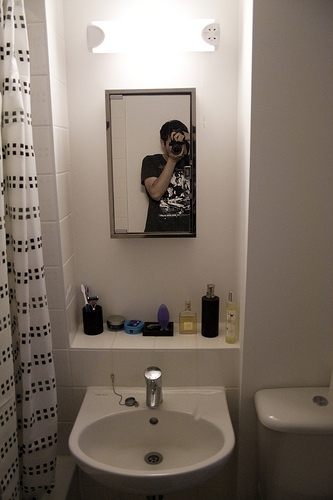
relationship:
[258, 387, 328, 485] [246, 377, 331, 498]
back of toilet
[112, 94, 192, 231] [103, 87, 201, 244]
mirror has frame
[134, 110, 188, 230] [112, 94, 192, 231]
reflection in mirror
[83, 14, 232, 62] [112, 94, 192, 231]
lights above mirror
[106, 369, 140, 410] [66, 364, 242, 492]
plug for sink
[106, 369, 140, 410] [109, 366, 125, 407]
plug has chain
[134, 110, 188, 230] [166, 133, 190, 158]
reflection with camera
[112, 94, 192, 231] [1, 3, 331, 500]
mirror in bathroom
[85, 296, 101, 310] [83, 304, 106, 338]
shaver in cup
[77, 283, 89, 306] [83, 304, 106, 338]
toothbrush in cup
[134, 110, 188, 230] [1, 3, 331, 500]
reflection in bathroom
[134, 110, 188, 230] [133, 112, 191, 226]
reflection on man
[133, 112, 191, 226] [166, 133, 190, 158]
man using camera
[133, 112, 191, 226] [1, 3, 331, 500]
man in bathroom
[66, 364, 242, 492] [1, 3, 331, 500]
sink in bathroom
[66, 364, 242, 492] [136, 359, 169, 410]
sink has faucet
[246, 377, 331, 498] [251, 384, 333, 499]
toilet has toilet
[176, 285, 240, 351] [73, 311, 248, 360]
bottles on shelf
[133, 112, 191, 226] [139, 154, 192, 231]
man wearing shirt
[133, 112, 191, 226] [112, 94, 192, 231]
man in mirror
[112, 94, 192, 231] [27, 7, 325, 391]
mirror on wall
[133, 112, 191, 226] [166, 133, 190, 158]
man holding camera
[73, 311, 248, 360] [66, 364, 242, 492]
shelf above sink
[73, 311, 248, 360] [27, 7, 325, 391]
shelf on wall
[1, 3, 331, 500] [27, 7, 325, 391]
bathroom has wall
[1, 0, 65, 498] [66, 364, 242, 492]
shower curtain next to sink